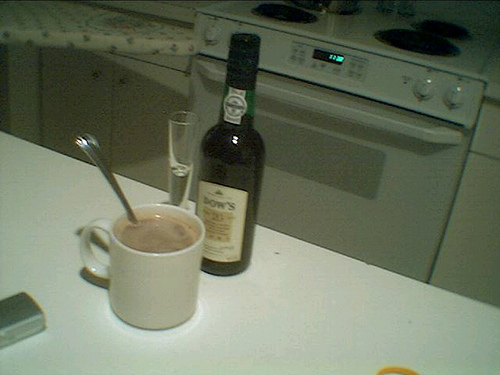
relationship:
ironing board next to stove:
[2, 1, 207, 61] [196, 3, 498, 250]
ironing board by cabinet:
[2, 1, 207, 61] [22, 40, 201, 191]